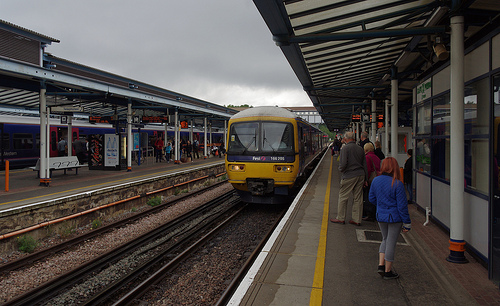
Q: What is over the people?
A: A metal and plastic awning.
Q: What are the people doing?
A: Waiting on the train.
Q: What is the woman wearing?
A: A blue jacket.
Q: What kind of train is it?
A: A yellow train.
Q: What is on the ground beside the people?
A: A yellow line.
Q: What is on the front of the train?
A: Head lights.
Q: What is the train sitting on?
A: Train tracks.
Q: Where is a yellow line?
A: On the platform.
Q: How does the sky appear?
A: Gray and cloudy.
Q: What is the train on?
A: Train tracks.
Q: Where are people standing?
A: On train platform.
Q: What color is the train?
A: Yellow.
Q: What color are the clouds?
A: Grey.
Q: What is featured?
A: Train.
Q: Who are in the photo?
A: People.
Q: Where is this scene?
A: Train station.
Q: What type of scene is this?
A: Outdoor.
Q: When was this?
A: Daytime.